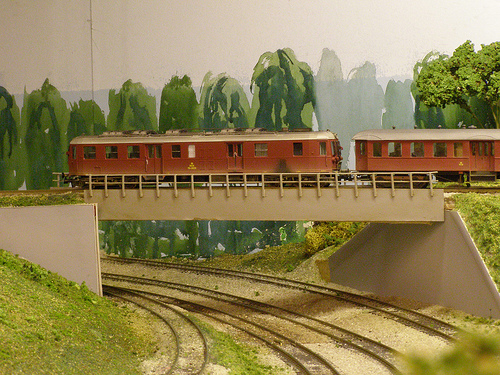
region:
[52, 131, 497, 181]
red train on bridge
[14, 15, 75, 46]
white clouds in blue sky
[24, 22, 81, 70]
white clouds in blue sky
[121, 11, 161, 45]
white clouds in blue sky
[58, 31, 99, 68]
white clouds in blue sky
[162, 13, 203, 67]
white clouds in blue sky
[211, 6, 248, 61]
white clouds in blue sky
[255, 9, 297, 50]
white clouds in blue sky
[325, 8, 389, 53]
white clouds in blue sky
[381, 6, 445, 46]
white clouds in blue sky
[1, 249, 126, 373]
A small grassy hill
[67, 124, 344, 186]
A red toy train car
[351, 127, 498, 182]
A red toy train car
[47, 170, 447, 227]
A small white bridge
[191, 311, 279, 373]
A small patch of grass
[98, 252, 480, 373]
some railroad tracks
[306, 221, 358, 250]
A small group of bushes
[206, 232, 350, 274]
A small grassy hill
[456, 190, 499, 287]
A small grassy hill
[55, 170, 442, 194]
some guard rails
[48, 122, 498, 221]
a miniature train on display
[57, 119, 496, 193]
a passenger train on display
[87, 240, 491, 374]
a miniature railroad track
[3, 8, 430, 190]
a painted backdrop for a train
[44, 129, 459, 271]
a train on a bridge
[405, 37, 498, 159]
miniature tree behind a train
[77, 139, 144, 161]
windows on a train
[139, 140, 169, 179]
a door on a train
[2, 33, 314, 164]
painting of trees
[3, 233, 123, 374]
a hillside on a miniature train set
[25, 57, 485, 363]
this picture has been edited with photo altering software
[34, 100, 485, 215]
trains on a bridge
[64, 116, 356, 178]
a brown painted train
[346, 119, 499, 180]
a train over the tracks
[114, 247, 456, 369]
tracks on the ground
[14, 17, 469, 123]
painted trees in the photo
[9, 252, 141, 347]
real grass in the photo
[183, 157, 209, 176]
a yellow sign on a train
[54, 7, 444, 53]
a hazy painted sky above the train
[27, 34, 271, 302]
this picture has real and fake elements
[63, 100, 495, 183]
the train is red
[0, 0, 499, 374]
scene is of a painting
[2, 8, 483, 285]
trees beside the train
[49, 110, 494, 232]
train is on a bridge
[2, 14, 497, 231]
trees are taller then bridge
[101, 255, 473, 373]
train tracks are brown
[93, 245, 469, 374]
rocks in between the tracks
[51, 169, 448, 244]
the bridge is brown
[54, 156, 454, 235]
bridge is made of concrete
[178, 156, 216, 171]
yellow sign on train